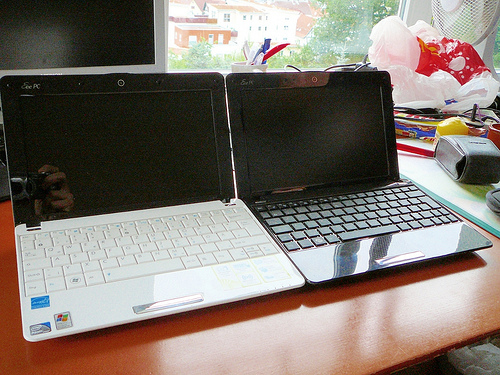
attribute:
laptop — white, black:
[1, 59, 303, 340]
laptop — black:
[208, 37, 494, 302]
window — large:
[162, 12, 414, 87]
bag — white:
[381, 15, 499, 102]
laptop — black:
[225, 53, 494, 289]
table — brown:
[4, 197, 499, 372]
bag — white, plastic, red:
[314, 21, 499, 90]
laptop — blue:
[2, 61, 462, 324]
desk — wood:
[7, 181, 492, 374]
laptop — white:
[223, 72, 494, 265]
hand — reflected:
[24, 158, 84, 223]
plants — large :
[314, 8, 374, 61]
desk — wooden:
[0, 113, 497, 370]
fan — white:
[429, 0, 499, 81]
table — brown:
[0, 154, 498, 374]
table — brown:
[252, 293, 493, 363]